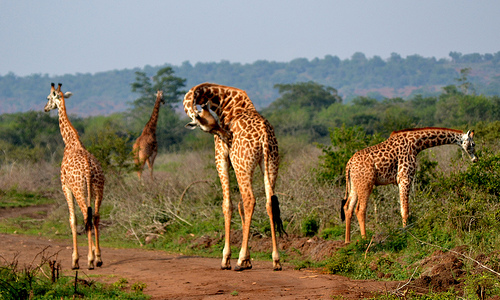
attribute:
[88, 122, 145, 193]
full bush — large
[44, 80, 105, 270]
giraffe — young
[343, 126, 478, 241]
giraffe — young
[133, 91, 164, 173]
giraffe — adult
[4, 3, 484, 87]
sky — blue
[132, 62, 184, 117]
tree — large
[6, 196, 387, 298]
trail — dirt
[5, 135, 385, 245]
grass — tall, grey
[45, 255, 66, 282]
twig — small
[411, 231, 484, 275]
stick — long